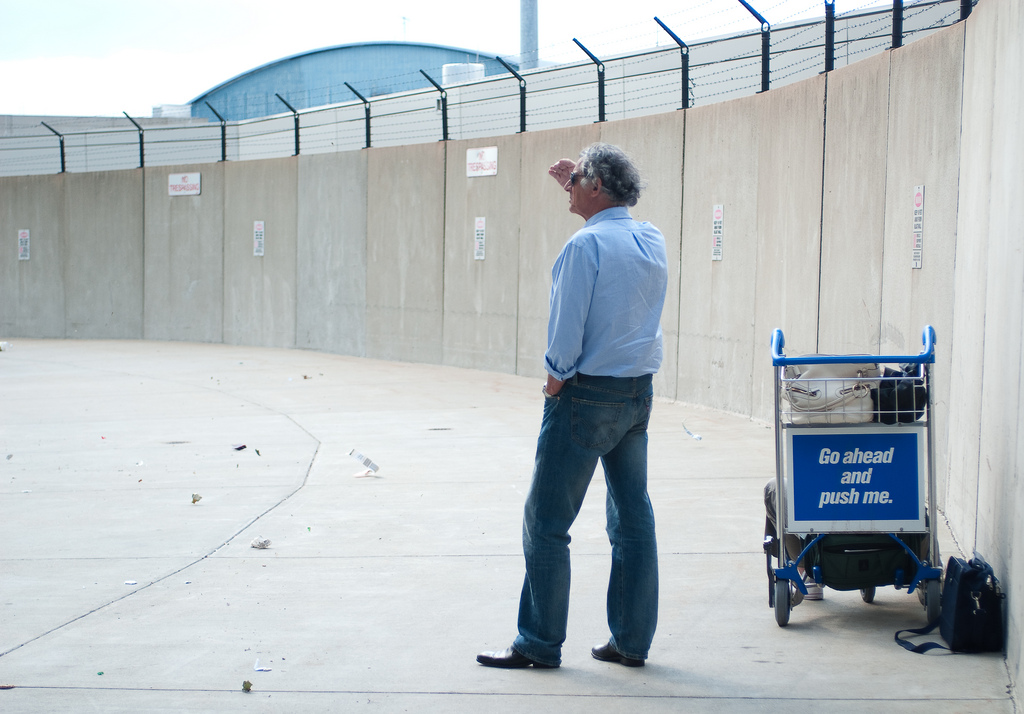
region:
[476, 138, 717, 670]
The man is wearing a blue shirt.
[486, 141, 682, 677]
The man is wearing blue pants.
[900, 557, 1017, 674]
A bag is up against the wall.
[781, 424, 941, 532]
The sign is blue and white.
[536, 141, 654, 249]
The man is wearing sunglasses.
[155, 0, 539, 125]
The building is blue.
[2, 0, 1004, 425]
The cement wall has a fence on top of it.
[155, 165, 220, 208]
A sign is posted on the wall.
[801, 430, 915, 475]
"Go ahead" written on a sign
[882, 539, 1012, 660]
Black bag with a strap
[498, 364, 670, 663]
A pair of blue jeans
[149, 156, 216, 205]
White sign attached to the wall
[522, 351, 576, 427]
A hand in a pocket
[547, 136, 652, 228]
Man is wearing sunglasses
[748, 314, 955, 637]
Bags on a cart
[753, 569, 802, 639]
A round black wheel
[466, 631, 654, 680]
A pair of black shoes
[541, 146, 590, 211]
a man with his hand raised to his face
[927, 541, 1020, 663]
a black bag on the ground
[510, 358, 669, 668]
a man wearing blue jeans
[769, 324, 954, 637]
a cart with wheels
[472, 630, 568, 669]
a man wearing black boots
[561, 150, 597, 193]
a man wearing sunglasses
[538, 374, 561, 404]
a man with his hand in his pants pocket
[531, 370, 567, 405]
a man wearing a wrist watch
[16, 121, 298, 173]
a fence on top of concrete wall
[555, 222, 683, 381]
The man is wearing a blue shirt.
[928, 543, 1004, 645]
A black bag on the ground.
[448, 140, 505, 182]
A sign on the wall.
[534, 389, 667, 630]
The man is wearing blue jeans.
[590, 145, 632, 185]
The man has grey and black hair.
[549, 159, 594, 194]
The man is wearing sunglasses.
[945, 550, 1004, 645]
The bag is black.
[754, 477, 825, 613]
A person leg on the cart.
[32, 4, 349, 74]
The sky is clear and blue.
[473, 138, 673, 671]
Man is standing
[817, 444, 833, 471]
A letter on a sign.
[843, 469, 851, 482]
A letter on a sign.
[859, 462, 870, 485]
A letter on a sign.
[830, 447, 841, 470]
A letter on a sign.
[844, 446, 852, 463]
A letter on a sign.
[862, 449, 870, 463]
A letter on a sign.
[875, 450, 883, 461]
A letter on a sign.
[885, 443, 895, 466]
A letter on a sign.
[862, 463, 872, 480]
A letter on a sign.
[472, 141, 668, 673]
the man is standing up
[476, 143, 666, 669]
the man has gray hair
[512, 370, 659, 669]
the denim jeans are blue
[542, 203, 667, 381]
the long sleeved shirt is blue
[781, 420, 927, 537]
the sign is blue and white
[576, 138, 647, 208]
the hair is gray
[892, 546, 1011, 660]
the black bag has a strap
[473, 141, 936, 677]
the luggage cart near the man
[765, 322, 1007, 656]
the bag near the luggage cart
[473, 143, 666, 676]
the man is wearing sunglasses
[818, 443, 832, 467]
A letter on a sign.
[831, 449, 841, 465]
A letter on a sign.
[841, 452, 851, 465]
A letter on a sign.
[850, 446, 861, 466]
A letter on a sign.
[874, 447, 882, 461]
A letter on a sign.